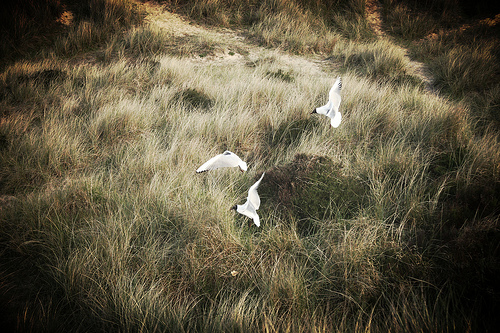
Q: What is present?
A: Birds.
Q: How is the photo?
A: Clear.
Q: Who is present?
A: Nobody.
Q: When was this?
A: Daytime.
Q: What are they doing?
A: Flying.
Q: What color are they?
A: White.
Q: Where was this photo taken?
A: In a marsh.